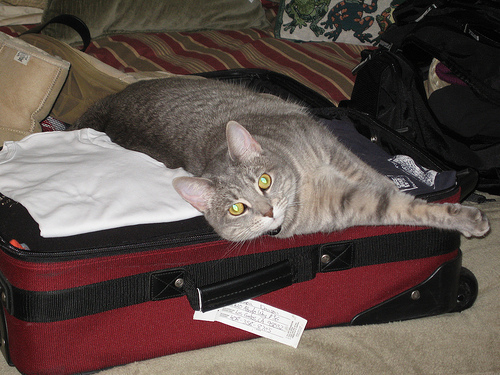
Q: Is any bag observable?
A: Yes, there is a bag.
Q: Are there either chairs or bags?
A: Yes, there is a bag.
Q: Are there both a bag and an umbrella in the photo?
A: No, there is a bag but no umbrellas.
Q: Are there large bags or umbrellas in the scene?
A: Yes, there is a large bag.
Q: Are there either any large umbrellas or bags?
A: Yes, there is a large bag.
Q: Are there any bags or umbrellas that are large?
A: Yes, the bag is large.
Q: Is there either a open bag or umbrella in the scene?
A: Yes, there is an open bag.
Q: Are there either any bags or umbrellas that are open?
A: Yes, the bag is open.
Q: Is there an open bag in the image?
A: Yes, there is an open bag.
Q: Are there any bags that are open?
A: Yes, there is a bag that is open.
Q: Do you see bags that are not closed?
A: Yes, there is a open bag.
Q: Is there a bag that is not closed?
A: Yes, there is a open bag.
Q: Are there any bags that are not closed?
A: Yes, there is a open bag.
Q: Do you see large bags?
A: Yes, there is a large bag.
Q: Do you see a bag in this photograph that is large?
A: Yes, there is a bag that is large.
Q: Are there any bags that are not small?
A: Yes, there is a large bag.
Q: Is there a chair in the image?
A: No, there are no chairs.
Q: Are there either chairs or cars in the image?
A: No, there are no chairs or cars.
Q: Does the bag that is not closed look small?
A: No, the bag is large.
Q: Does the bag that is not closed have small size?
A: No, the bag is large.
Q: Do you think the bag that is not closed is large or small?
A: The bag is large.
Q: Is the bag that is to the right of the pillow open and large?
A: Yes, the bag is open and large.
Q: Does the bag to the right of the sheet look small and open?
A: No, the bag is open but large.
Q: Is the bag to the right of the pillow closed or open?
A: The bag is open.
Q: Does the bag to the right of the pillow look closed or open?
A: The bag is open.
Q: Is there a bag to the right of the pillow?
A: Yes, there is a bag to the right of the pillow.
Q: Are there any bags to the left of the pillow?
A: No, the bag is to the right of the pillow.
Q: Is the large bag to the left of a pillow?
A: No, the bag is to the right of a pillow.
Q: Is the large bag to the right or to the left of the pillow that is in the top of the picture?
A: The bag is to the right of the pillow.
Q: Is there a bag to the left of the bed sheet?
A: No, the bag is to the right of the bed sheet.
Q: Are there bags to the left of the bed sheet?
A: No, the bag is to the right of the bed sheet.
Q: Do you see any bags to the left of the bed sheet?
A: No, the bag is to the right of the bed sheet.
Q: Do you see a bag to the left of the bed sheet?
A: No, the bag is to the right of the bed sheet.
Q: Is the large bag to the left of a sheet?
A: No, the bag is to the right of a sheet.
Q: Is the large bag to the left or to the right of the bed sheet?
A: The bag is to the right of the bed sheet.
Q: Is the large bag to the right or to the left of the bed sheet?
A: The bag is to the right of the bed sheet.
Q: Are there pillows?
A: Yes, there is a pillow.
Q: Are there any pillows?
A: Yes, there is a pillow.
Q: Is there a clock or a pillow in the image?
A: Yes, there is a pillow.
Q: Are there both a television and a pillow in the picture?
A: No, there is a pillow but no televisions.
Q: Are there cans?
A: No, there are no cans.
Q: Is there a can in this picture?
A: No, there are no cans.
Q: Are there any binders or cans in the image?
A: No, there are no cans or binders.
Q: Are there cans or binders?
A: No, there are no cans or binders.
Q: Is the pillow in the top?
A: Yes, the pillow is in the top of the image.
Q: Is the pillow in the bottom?
A: No, the pillow is in the top of the image.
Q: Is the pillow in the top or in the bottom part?
A: The pillow is in the top of the image.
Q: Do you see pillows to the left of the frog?
A: Yes, there is a pillow to the left of the frog.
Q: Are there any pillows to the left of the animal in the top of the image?
A: Yes, there is a pillow to the left of the frog.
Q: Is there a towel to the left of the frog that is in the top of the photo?
A: No, there is a pillow to the left of the frog.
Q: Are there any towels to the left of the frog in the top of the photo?
A: No, there is a pillow to the left of the frog.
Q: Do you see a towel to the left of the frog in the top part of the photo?
A: No, there is a pillow to the left of the frog.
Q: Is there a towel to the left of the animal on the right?
A: No, there is a pillow to the left of the frog.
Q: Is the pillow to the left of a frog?
A: Yes, the pillow is to the left of a frog.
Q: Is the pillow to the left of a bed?
A: No, the pillow is to the left of a frog.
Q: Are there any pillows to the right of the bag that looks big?
A: No, the pillow is to the left of the bag.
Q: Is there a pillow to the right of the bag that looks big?
A: No, the pillow is to the left of the bag.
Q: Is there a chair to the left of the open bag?
A: No, there is a pillow to the left of the bag.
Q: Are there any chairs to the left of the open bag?
A: No, there is a pillow to the left of the bag.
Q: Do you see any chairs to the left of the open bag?
A: No, there is a pillow to the left of the bag.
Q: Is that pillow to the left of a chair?
A: No, the pillow is to the left of the bag.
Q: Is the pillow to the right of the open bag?
A: No, the pillow is to the left of the bag.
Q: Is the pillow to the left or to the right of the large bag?
A: The pillow is to the left of the bag.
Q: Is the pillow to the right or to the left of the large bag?
A: The pillow is to the left of the bag.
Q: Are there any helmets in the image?
A: No, there are no helmets.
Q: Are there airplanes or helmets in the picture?
A: No, there are no helmets or airplanes.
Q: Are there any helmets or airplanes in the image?
A: No, there are no helmets or airplanes.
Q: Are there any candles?
A: No, there are no candles.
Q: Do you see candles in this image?
A: No, there are no candles.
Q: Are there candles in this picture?
A: No, there are no candles.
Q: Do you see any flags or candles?
A: No, there are no candles or flags.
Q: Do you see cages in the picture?
A: No, there are no cages.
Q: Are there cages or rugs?
A: No, there are no cages or rugs.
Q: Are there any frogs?
A: Yes, there is a frog.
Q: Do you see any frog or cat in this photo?
A: Yes, there is a frog.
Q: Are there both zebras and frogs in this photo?
A: No, there is a frog but no zebras.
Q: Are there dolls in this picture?
A: No, there are no dolls.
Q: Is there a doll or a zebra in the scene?
A: No, there are no dolls or zebras.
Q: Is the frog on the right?
A: Yes, the frog is on the right of the image.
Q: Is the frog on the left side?
A: No, the frog is on the right of the image.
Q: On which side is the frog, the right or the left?
A: The frog is on the right of the image.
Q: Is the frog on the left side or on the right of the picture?
A: The frog is on the right of the image.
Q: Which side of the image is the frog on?
A: The frog is on the right of the image.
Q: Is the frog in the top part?
A: Yes, the frog is in the top of the image.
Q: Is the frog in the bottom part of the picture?
A: No, the frog is in the top of the image.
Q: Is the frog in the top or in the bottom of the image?
A: The frog is in the top of the image.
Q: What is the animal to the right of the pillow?
A: The animal is a frog.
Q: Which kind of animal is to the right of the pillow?
A: The animal is a frog.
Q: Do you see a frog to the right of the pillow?
A: Yes, there is a frog to the right of the pillow.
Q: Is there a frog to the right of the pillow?
A: Yes, there is a frog to the right of the pillow.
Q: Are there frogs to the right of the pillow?
A: Yes, there is a frog to the right of the pillow.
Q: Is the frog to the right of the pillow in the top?
A: Yes, the frog is to the right of the pillow.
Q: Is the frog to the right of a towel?
A: No, the frog is to the right of the pillow.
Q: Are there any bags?
A: Yes, there is a bag.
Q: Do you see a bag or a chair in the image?
A: Yes, there is a bag.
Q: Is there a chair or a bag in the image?
A: Yes, there is a bag.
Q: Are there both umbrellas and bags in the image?
A: No, there is a bag but no umbrellas.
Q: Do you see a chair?
A: No, there are no chairs.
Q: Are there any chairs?
A: No, there are no chairs.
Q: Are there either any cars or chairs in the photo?
A: No, there are no chairs or cars.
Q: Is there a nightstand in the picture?
A: No, there are no nightstands.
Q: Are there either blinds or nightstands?
A: No, there are no nightstands or blinds.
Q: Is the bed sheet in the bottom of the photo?
A: No, the bed sheet is in the top of the image.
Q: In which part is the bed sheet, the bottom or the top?
A: The bed sheet is in the top of the image.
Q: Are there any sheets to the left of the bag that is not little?
A: Yes, there is a sheet to the left of the bag.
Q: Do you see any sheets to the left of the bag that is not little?
A: Yes, there is a sheet to the left of the bag.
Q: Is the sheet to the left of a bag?
A: Yes, the sheet is to the left of a bag.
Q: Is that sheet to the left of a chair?
A: No, the sheet is to the left of a bag.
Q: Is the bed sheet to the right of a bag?
A: No, the bed sheet is to the left of a bag.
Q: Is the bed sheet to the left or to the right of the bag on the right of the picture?
A: The bed sheet is to the left of the bag.